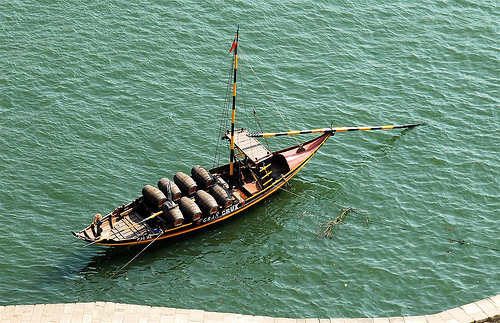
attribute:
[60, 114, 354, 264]
sailboat — empty, brown, wooden, tied, docked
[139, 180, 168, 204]
barrel — large, wooden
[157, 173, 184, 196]
barrel — wooden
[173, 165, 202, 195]
barrel — large, wooden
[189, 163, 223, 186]
barrel — wooden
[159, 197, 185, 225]
barrel — wooden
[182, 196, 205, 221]
barrel — wooden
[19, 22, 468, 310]
water — green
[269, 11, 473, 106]
water — green, blue, calm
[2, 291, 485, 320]
wall — brick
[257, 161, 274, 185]
ladder — yellow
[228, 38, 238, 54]
flag — red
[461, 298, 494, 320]
bricks — white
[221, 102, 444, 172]
sail — broken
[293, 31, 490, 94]
waves — green